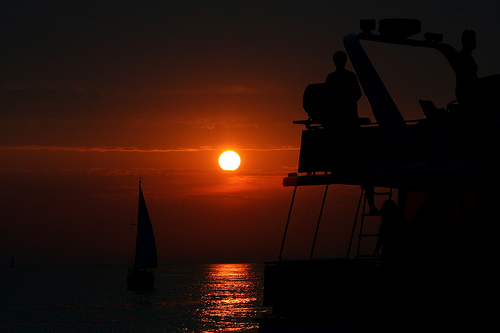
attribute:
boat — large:
[255, 28, 468, 289]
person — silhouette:
[312, 47, 374, 130]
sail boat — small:
[121, 169, 159, 289]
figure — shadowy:
[322, 47, 362, 126]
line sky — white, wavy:
[10, 133, 293, 160]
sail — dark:
[122, 175, 162, 298]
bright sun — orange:
[216, 148, 243, 173]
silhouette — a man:
[325, 50, 362, 130]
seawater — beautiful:
[192, 256, 265, 329]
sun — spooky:
[192, 131, 262, 183]